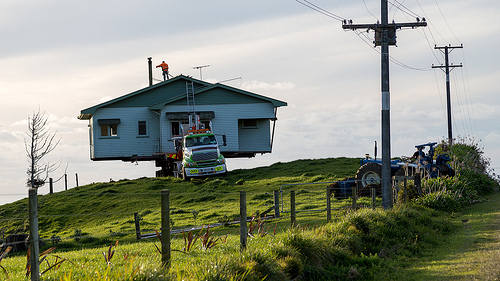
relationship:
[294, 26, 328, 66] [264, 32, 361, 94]
cloud cover in sky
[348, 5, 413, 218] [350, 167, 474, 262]
pole on grass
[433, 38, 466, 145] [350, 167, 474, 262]
pole on grass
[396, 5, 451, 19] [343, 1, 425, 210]
wires above pole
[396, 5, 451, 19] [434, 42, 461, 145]
wires above pole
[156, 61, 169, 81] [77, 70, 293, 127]
man standing on roof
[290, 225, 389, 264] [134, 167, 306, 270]
weeds in grass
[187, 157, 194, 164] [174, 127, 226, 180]
headlight on truck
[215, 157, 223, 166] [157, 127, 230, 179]
right headlight on truck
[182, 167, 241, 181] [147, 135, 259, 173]
front fender of truck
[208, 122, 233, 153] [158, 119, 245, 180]
mirror on truck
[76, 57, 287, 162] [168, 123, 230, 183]
house on top truck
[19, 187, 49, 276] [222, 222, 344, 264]
pole in grass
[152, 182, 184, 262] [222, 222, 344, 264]
pole in grass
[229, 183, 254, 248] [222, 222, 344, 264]
pole in grass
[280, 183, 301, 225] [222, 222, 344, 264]
pole in grass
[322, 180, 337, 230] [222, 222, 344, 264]
pole in grass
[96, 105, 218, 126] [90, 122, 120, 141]
awnings on top windows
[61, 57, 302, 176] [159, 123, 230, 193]
house on truck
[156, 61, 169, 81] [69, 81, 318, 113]
man on roof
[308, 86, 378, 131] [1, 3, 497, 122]
clouds in sky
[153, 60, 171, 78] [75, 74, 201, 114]
man on roof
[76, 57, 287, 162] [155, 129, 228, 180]
house on truck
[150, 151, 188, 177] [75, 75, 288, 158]
truck bed under house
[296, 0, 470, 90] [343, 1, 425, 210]
wire on pole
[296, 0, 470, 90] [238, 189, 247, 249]
wire on pole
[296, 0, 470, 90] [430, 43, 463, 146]
wire on pole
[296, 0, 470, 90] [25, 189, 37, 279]
wire on pole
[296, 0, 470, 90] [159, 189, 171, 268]
wire on pole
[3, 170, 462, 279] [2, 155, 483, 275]
gate surrounding property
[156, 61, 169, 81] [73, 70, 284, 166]
man on top house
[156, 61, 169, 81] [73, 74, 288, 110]
man on top roof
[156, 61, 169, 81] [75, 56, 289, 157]
man on top house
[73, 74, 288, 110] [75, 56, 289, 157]
roof on top house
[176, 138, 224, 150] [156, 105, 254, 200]
window on truck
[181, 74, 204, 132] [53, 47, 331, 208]
ladder leaning against house